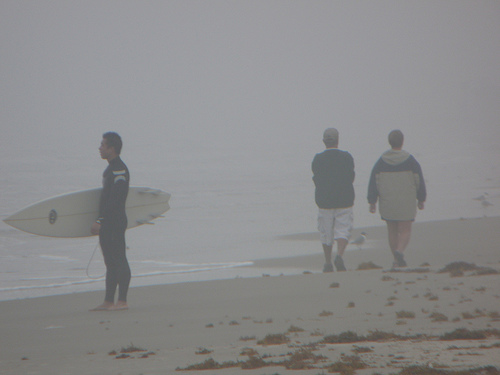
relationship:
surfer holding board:
[77, 120, 142, 324] [19, 192, 106, 243]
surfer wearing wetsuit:
[77, 120, 142, 324] [96, 162, 134, 298]